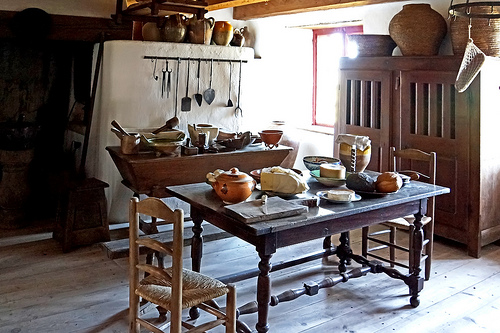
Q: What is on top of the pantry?
A: Large baskets.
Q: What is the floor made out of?
A: Wood.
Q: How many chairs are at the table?
A: Two.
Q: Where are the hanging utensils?
A: On the white wall.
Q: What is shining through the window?
A: The sun.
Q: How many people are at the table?
A: None.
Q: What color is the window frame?
A: Red.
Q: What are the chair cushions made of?
A: Wicker.